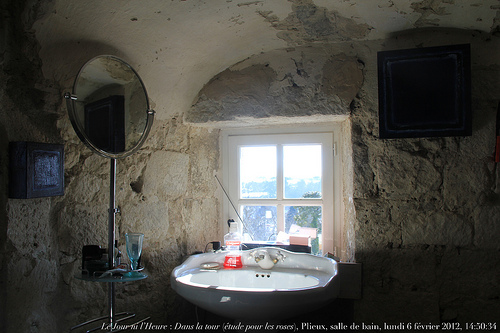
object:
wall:
[0, 0, 497, 332]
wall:
[357, 107, 492, 266]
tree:
[291, 190, 322, 256]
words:
[100, 321, 497, 330]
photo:
[0, 2, 499, 333]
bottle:
[223, 222, 245, 270]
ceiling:
[0, 0, 499, 124]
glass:
[120, 232, 147, 278]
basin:
[169, 246, 339, 325]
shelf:
[76, 232, 149, 282]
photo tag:
[87, 321, 497, 331]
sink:
[169, 246, 340, 333]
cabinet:
[1, 143, 65, 200]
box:
[377, 43, 477, 139]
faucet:
[249, 249, 287, 269]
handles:
[249, 247, 287, 269]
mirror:
[71, 54, 151, 158]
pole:
[106, 156, 118, 331]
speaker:
[375, 44, 474, 139]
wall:
[0, 34, 497, 331]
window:
[223, 134, 330, 252]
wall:
[357, 136, 494, 325]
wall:
[3, 101, 205, 331]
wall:
[192, 44, 377, 114]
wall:
[241, 60, 333, 105]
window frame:
[219, 122, 341, 265]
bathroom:
[0, 2, 499, 333]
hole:
[255, 274, 259, 278]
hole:
[261, 275, 264, 278]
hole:
[267, 275, 271, 278]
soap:
[198, 262, 222, 273]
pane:
[237, 200, 278, 243]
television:
[375, 51, 482, 140]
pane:
[237, 142, 278, 200]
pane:
[281, 142, 324, 201]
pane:
[232, 200, 279, 245]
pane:
[281, 205, 325, 258]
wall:
[114, 26, 418, 286]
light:
[238, 144, 322, 184]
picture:
[0, 0, 499, 333]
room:
[0, 0, 500, 332]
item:
[223, 221, 245, 268]